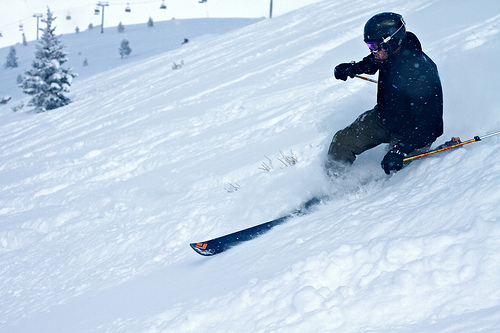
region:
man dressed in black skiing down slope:
[324, 10, 446, 188]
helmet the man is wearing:
[361, 12, 404, 62]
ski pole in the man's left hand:
[401, 132, 498, 162]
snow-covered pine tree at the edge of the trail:
[24, 6, 76, 111]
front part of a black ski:
[191, 194, 341, 257]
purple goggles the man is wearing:
[360, 33, 387, 50]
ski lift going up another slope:
[2, 0, 213, 33]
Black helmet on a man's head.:
[362, 12, 408, 48]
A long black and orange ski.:
[187, 134, 464, 257]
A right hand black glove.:
[333, 59, 356, 81]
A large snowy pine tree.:
[22, 6, 77, 113]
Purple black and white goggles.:
[363, 21, 405, 55]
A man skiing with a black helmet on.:
[324, 12, 445, 196]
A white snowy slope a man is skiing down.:
[0, 4, 499, 331]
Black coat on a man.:
[364, 37, 443, 155]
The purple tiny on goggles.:
[365, 39, 379, 52]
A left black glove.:
[379, 147, 405, 177]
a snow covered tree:
[20, 10, 81, 115]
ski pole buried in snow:
[370, 125, 496, 175]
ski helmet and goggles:
[357, 10, 412, 56]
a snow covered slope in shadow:
[3, 12, 268, 102]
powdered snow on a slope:
[0, 125, 158, 195]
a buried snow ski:
[185, 173, 340, 259]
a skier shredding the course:
[185, 10, 496, 255]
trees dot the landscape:
[2, 5, 204, 120]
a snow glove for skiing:
[377, 137, 417, 178]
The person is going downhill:
[161, 10, 477, 261]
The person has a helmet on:
[353, 8, 415, 65]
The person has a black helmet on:
[354, 4, 416, 76]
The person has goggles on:
[361, 25, 409, 55]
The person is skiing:
[174, 8, 475, 266]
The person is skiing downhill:
[188, 6, 485, 258]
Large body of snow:
[14, 128, 155, 265]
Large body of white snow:
[23, 141, 149, 271]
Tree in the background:
[11, 4, 89, 124]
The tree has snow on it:
[12, 8, 82, 114]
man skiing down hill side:
[326, 3, 454, 213]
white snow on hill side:
[389, 269, 454, 326]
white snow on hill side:
[39, 125, 86, 176]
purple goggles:
[363, 37, 388, 53]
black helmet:
[362, 3, 412, 48]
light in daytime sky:
[0, 1, 302, 48]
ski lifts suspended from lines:
[1, 0, 213, 41]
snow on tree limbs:
[19, 5, 76, 111]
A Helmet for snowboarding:
[345, 3, 410, 66]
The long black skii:
[145, 105, 487, 265]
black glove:
[323, 50, 363, 97]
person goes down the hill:
[159, 3, 495, 268]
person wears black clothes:
[315, 2, 457, 185]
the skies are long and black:
[185, 158, 386, 278]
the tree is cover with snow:
[16, 3, 80, 120]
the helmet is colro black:
[352, 6, 416, 74]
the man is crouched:
[313, 4, 455, 194]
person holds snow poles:
[311, 2, 498, 192]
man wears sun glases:
[348, 6, 425, 88]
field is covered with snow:
[6, 2, 488, 329]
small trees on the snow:
[66, 6, 195, 71]